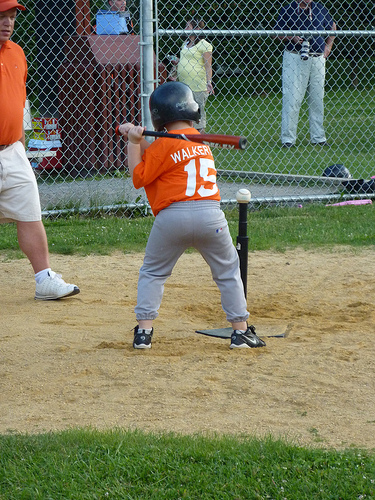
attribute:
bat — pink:
[298, 198, 372, 209]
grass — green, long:
[279, 213, 339, 241]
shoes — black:
[228, 326, 267, 348]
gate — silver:
[224, 55, 268, 97]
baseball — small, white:
[233, 185, 252, 205]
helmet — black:
[139, 74, 219, 137]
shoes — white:
[19, 238, 88, 301]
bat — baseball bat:
[122, 121, 245, 159]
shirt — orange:
[129, 128, 224, 215]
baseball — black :
[233, 187, 250, 203]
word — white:
[162, 142, 218, 159]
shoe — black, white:
[230, 327, 266, 347]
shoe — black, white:
[133, 325, 152, 348]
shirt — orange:
[1, 39, 28, 154]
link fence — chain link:
[54, 9, 359, 199]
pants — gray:
[136, 197, 249, 322]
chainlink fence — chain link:
[10, 2, 374, 215]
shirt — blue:
[274, 0, 336, 53]